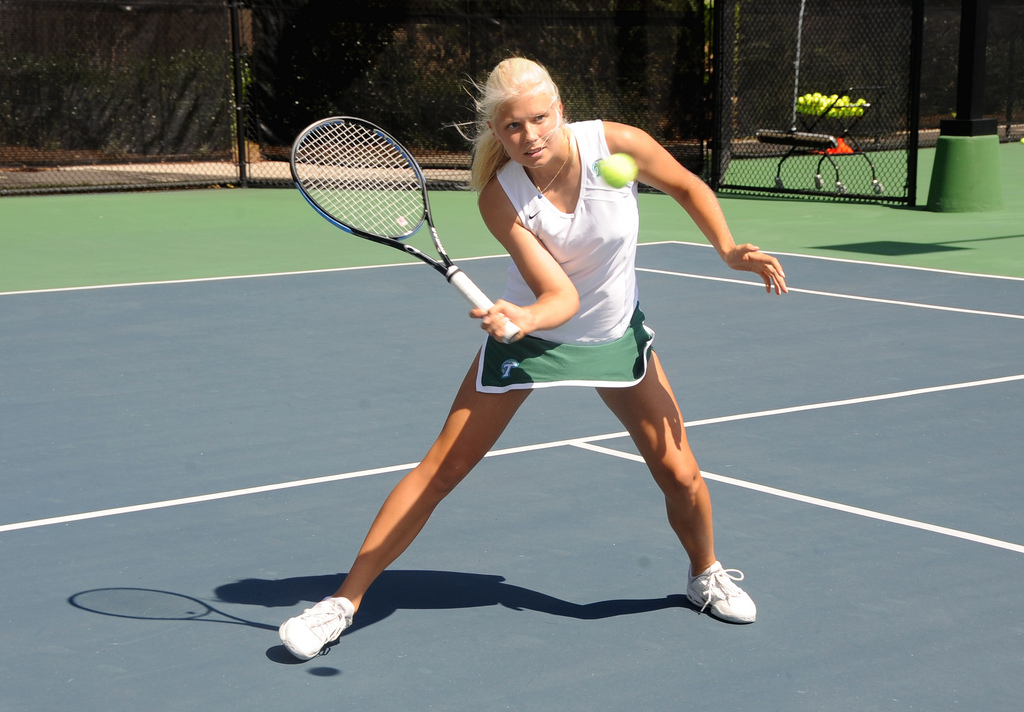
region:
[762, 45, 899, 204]
a basket full of tennis balls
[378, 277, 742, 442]
A green tennis skirt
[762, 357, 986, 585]
White lines on the tennis court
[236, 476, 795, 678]
A player has on white sneakers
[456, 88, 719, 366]
Player is wearing white tank top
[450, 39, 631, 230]
Player has blonde hair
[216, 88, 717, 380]
Player holding a tennis racket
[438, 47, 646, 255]
A woman has a ponytail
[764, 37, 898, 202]
Many tennis balls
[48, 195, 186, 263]
Green on the tennis court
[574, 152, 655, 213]
Tennis ball flying in the air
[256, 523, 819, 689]
Pair of white sneakers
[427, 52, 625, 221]
Girl has blonde hair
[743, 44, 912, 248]
Bunch of tennis balls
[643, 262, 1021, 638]
White lines on the tennis court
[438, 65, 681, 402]
A white tank top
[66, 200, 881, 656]
Green and blue clay tennis court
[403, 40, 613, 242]
Girl's hair is in a ponytail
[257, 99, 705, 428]
Player is holding a tennis racket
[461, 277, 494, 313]
white handle of tennis racket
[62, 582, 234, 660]
shadow of tennis racket on the ground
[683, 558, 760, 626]
woman wearing white tennis shoes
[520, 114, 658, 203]
tennis ball near woman's face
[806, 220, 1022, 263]
shadow of square sign on the ground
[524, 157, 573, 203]
woman wearing thin necklace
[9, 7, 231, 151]
dark wall beyond fence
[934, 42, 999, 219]
large black pole on green base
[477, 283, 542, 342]
woman holding racket with her right hand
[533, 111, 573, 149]
woman's blonde hair falling across her face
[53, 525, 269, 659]
the shadow of a tennis racket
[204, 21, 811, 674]
a young woman playing tennis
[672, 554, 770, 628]
a white shoe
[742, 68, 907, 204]
a basket of tennis balls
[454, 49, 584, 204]
a woman with blond hair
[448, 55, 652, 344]
a woman wearing a white tank top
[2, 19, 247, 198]
a black chain link fence around a tennis court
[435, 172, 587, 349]
a tennis player's arm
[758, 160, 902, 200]
wheels on a cart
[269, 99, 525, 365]
A tennis racket in girl's hand.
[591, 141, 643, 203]
Tennis ball in motion on court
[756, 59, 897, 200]
Basket of tennis balls.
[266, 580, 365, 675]
Shoe on the foot of athlete.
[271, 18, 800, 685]
Athlete playing tennis.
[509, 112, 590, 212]
gold chain on girl's neck.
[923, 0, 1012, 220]
light post on the court.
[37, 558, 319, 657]
Shadow of the tennis racket in girls hand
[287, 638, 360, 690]
Shadow of ball in the air.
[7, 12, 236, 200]
Chain link fence in the background.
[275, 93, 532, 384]
A black and white tennis racket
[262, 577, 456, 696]
A white tennis shoe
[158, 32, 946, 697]
A girl playing tennis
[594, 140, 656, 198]
a tennis ball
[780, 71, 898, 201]
A cart of tennis balls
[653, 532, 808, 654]
A white tennis shoe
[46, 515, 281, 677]
A tennis racket's shadow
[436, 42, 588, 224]
A girl with blonde hair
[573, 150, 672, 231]
Ball is flying in the air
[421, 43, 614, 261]
A woman is blonde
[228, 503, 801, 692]
Player has on white sneakers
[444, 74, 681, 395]
Player has on a white tank top